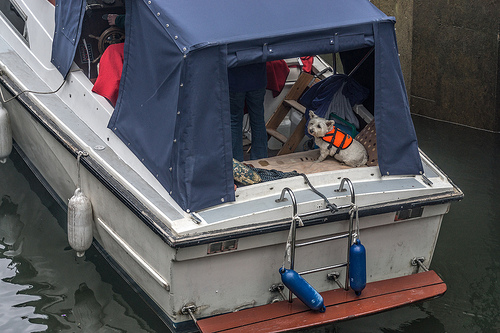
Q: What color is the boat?
A: White.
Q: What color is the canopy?
A: Blue.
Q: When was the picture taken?
A: In the daytime.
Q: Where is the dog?
A: On the boat.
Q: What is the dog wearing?
A: A life vest.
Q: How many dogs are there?
A: One.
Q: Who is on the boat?
A: A man and a dog.